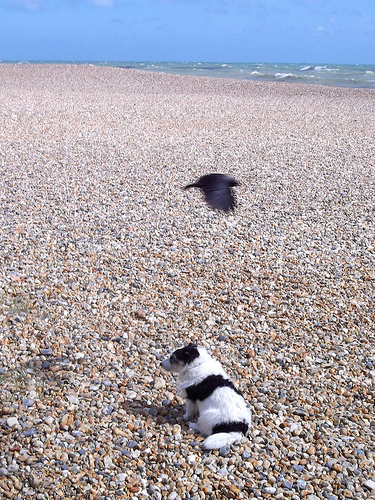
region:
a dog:
[157, 338, 253, 445]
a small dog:
[157, 338, 256, 452]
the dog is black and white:
[156, 340, 255, 449]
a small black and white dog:
[156, 337, 254, 452]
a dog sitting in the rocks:
[126, 333, 275, 457]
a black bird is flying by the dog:
[181, 163, 246, 221]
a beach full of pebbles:
[2, 51, 373, 490]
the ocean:
[7, 51, 373, 106]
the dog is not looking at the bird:
[158, 339, 274, 468]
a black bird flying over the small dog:
[120, 160, 319, 472]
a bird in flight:
[183, 154, 263, 241]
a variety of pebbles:
[16, 421, 143, 487]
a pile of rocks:
[26, 424, 178, 495]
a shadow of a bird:
[1, 346, 94, 400]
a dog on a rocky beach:
[106, 336, 282, 464]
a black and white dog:
[150, 325, 260, 449]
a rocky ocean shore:
[29, 20, 374, 193]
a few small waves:
[189, 52, 343, 90]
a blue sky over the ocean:
[83, 4, 307, 80]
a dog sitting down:
[150, 291, 261, 453]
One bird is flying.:
[172, 155, 243, 223]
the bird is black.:
[177, 163, 249, 221]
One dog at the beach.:
[155, 333, 255, 459]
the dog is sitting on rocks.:
[146, 328, 253, 446]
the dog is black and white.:
[155, 328, 255, 452]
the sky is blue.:
[4, 0, 372, 83]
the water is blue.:
[105, 48, 367, 104]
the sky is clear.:
[2, 2, 371, 67]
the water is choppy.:
[106, 48, 373, 102]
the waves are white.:
[246, 55, 373, 87]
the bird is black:
[173, 166, 256, 219]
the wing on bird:
[194, 150, 242, 218]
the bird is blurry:
[191, 169, 242, 220]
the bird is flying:
[173, 166, 239, 230]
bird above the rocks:
[167, 165, 283, 295]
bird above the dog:
[156, 168, 299, 470]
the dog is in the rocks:
[156, 344, 275, 488]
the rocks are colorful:
[42, 368, 178, 469]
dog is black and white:
[161, 342, 269, 450]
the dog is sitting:
[159, 343, 272, 467]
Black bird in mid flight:
[163, 158, 259, 220]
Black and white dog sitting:
[156, 335, 261, 455]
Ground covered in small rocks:
[45, 200, 126, 296]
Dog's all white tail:
[195, 427, 248, 451]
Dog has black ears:
[178, 336, 202, 363]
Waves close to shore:
[237, 62, 374, 88]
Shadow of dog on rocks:
[110, 381, 184, 435]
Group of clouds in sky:
[215, 4, 348, 43]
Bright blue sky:
[14, 23, 128, 59]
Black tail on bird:
[173, 170, 199, 198]